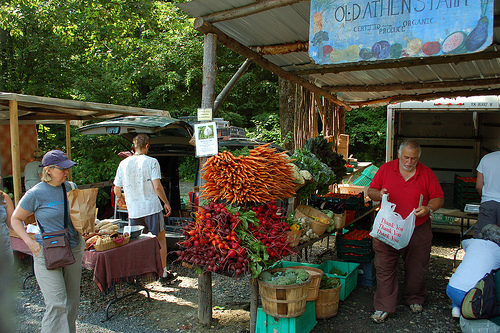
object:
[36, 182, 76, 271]
bag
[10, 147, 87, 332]
woman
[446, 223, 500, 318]
person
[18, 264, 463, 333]
floor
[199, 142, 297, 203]
carrot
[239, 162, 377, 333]
shelf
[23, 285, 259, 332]
ground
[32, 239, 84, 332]
pants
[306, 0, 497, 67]
sign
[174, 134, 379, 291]
vegetable stand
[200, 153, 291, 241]
vegetables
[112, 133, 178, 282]
man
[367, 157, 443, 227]
red shirt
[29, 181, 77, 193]
shoulder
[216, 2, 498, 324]
stall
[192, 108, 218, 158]
sign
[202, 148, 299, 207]
veggy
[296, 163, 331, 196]
veggy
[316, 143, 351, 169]
veggy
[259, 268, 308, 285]
vegetable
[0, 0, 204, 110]
leaves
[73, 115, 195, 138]
hatch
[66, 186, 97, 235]
bag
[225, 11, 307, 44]
metal roof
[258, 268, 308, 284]
vegetables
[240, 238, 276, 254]
vegetables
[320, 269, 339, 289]
vegetables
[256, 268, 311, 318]
basket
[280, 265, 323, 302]
basket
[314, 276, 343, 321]
basket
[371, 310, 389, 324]
shoe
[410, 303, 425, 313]
shoe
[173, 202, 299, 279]
radishes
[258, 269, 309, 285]
fruit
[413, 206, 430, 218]
hand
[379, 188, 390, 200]
hand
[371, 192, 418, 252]
bag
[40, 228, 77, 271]
purse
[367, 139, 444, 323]
man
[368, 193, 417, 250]
plastic bag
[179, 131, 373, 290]
vegetables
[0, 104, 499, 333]
market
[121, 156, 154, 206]
back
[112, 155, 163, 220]
t-shirt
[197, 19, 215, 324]
wooden pole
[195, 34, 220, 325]
post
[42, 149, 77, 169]
cap